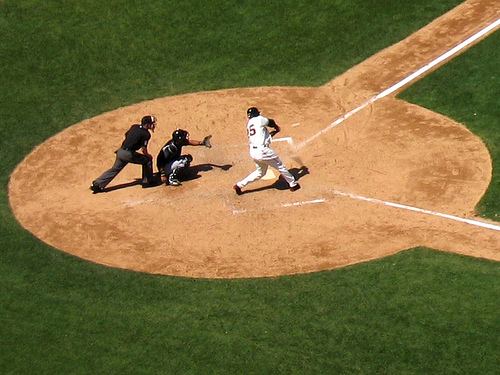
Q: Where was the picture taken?
A: At a baseball game.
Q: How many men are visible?
A: Three.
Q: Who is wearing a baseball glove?
A: The catcher in the middle.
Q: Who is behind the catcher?
A: The umpire.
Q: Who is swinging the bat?
A: The batter.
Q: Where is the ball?
A: Near the batter's swing.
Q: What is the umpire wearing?
A: Pants and shirt and a mask.